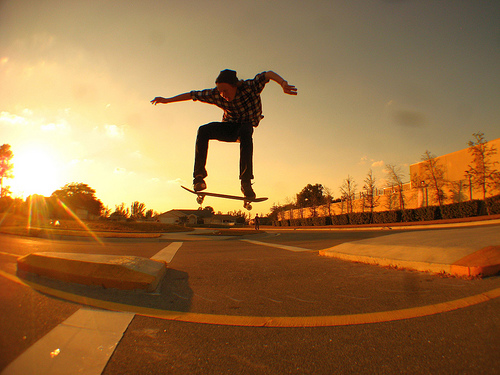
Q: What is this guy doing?
A: Skateboarding.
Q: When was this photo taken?
A: During the day.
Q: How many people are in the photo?
A: One.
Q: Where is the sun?
A: Setting in the background.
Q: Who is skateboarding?
A: A guy.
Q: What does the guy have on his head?
A: A hat.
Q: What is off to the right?
A: Trees.